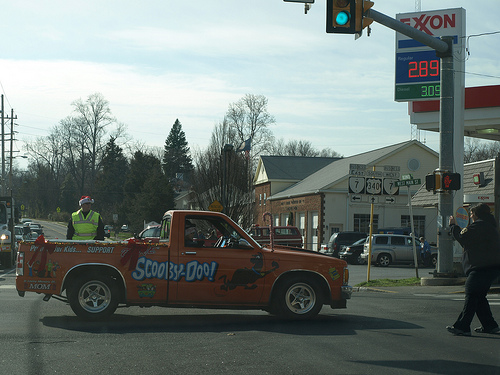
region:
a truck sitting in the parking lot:
[10, 213, 355, 321]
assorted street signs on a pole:
[343, 162, 401, 207]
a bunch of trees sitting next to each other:
[26, 100, 260, 207]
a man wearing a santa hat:
[61, 195, 108, 244]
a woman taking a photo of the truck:
[443, 200, 498, 342]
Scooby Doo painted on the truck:
[222, 246, 277, 298]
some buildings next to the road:
[246, 145, 440, 253]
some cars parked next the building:
[328, 229, 428, 261]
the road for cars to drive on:
[31, 215, 69, 240]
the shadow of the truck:
[35, 301, 395, 337]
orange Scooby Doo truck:
[11, 210, 356, 322]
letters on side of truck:
[128, 255, 218, 286]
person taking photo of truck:
[442, 201, 497, 332]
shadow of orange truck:
[35, 310, 430, 335]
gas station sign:
[390, 5, 465, 100]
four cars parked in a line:
[316, 229, 438, 269]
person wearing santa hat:
[65, 192, 105, 239]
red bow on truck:
[26, 232, 57, 279]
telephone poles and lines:
[1, 93, 60, 178]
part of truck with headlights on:
[0, 195, 15, 269]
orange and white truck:
[22, 208, 344, 345]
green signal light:
[317, 5, 354, 34]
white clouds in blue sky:
[9, 5, 51, 58]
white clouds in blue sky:
[12, 43, 73, 94]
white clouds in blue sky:
[73, 21, 125, 72]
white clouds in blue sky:
[132, 17, 185, 59]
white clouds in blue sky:
[127, 75, 169, 112]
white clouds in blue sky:
[172, 15, 236, 73]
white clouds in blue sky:
[223, 22, 309, 72]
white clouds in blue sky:
[279, 58, 338, 118]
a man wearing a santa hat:
[71, 192, 101, 214]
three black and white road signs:
[343, 159, 413, 209]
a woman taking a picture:
[440, 197, 492, 257]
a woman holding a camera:
[432, 194, 486, 248]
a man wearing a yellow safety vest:
[61, 194, 111, 236]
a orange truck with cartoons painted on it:
[0, 208, 374, 320]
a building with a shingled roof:
[246, 143, 401, 225]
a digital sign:
[396, 19, 454, 101]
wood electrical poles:
[0, 92, 20, 206]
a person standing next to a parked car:
[413, 234, 430, 269]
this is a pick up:
[12, 203, 372, 335]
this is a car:
[360, 228, 432, 270]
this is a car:
[338, 234, 418, 276]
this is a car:
[314, 223, 390, 277]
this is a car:
[2, 233, 46, 262]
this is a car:
[247, 205, 309, 267]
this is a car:
[107, 208, 142, 237]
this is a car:
[8, 212, 50, 247]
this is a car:
[10, 203, 373, 331]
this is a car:
[19, 215, 42, 237]